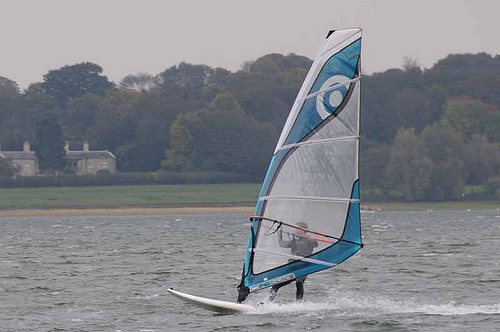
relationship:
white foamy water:
[244, 304, 320, 311] [2, 214, 500, 332]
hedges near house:
[0, 174, 266, 184] [0, 140, 119, 186]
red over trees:
[445, 92, 499, 111] [2, 54, 498, 200]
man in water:
[277, 222, 326, 303] [2, 214, 500, 332]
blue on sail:
[273, 39, 361, 174] [245, 28, 365, 290]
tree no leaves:
[116, 75, 162, 95] [121, 76, 163, 86]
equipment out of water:
[166, 27, 365, 310] [2, 214, 500, 332]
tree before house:
[33, 107, 70, 179] [0, 140, 119, 186]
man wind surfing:
[277, 222, 326, 303] [162, 221, 465, 316]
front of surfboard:
[164, 280, 252, 314] [163, 284, 385, 319]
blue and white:
[273, 39, 361, 174] [257, 92, 357, 269]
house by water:
[0, 140, 119, 186] [2, 214, 500, 332]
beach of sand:
[0, 203, 269, 218] [1, 206, 256, 213]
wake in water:
[241, 292, 495, 325] [2, 214, 500, 332]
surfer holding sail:
[277, 222, 326, 303] [245, 28, 365, 290]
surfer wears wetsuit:
[277, 222, 326, 303] [273, 229, 317, 291]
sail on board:
[245, 28, 365, 290] [163, 284, 385, 319]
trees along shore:
[2, 54, 498, 200] [365, 178, 499, 212]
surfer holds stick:
[277, 222, 326, 303] [248, 212, 365, 245]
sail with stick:
[245, 28, 365, 290] [248, 212, 365, 245]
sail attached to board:
[245, 28, 365, 290] [163, 284, 385, 319]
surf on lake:
[162, 221, 465, 316] [2, 214, 500, 332]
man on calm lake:
[277, 222, 326, 303] [2, 214, 500, 332]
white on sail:
[257, 92, 357, 269] [245, 28, 365, 290]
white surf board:
[257, 92, 357, 269] [167, 276, 312, 321]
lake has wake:
[2, 214, 500, 332] [241, 292, 495, 325]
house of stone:
[0, 140, 119, 186] [16, 160, 121, 179]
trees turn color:
[2, 54, 498, 200] [92, 81, 137, 149]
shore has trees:
[365, 178, 499, 212] [352, 105, 499, 209]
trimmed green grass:
[3, 184, 260, 207] [3, 183, 251, 207]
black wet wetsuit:
[287, 238, 314, 256] [273, 229, 317, 291]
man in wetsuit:
[277, 222, 326, 303] [273, 229, 317, 291]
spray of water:
[258, 285, 427, 306] [2, 214, 500, 332]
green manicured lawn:
[0, 186, 94, 206] [3, 184, 260, 207]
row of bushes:
[0, 172, 264, 189] [0, 174, 266, 184]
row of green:
[0, 172, 264, 189] [71, 178, 183, 187]